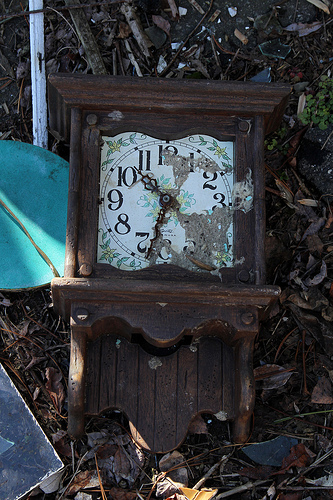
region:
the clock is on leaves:
[0, 0, 332, 498]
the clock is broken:
[91, 124, 257, 284]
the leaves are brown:
[0, 2, 332, 499]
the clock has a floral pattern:
[100, 130, 235, 269]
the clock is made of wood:
[47, 71, 280, 450]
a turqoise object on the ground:
[0, 138, 65, 291]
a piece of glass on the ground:
[0, 436, 15, 455]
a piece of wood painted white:
[26, 0, 45, 146]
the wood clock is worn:
[45, 72, 281, 452]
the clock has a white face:
[102, 135, 232, 266]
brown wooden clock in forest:
[43, 68, 296, 447]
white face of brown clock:
[52, 67, 289, 459]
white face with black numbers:
[96, 131, 236, 265]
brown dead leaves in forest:
[6, 0, 331, 495]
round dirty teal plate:
[1, 139, 75, 297]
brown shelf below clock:
[47, 68, 281, 469]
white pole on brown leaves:
[28, 0, 47, 158]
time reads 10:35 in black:
[92, 127, 242, 270]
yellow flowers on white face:
[93, 126, 239, 273]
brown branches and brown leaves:
[4, 2, 331, 498]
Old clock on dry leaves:
[35, 39, 284, 459]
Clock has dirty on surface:
[92, 116, 244, 277]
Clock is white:
[94, 131, 236, 275]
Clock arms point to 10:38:
[129, 160, 182, 259]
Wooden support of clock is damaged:
[38, 55, 286, 471]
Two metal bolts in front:
[61, 299, 264, 327]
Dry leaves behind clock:
[11, 2, 329, 494]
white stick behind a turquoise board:
[25, 1, 50, 156]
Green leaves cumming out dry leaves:
[271, 68, 332, 156]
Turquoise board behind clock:
[2, 132, 72, 298]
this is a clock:
[99, 134, 234, 268]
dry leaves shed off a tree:
[92, 454, 274, 498]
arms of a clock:
[131, 162, 175, 259]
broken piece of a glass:
[257, 37, 292, 59]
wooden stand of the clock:
[71, 360, 257, 451]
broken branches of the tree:
[197, 459, 268, 496]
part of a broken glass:
[1, 366, 67, 498]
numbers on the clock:
[107, 166, 136, 237]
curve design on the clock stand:
[90, 409, 159, 442]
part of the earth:
[111, 456, 196, 495]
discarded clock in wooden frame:
[44, 30, 300, 461]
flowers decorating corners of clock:
[84, 124, 237, 274]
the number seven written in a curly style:
[131, 225, 149, 254]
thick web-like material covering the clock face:
[139, 130, 252, 271]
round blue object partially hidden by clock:
[3, 120, 70, 302]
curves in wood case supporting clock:
[63, 293, 255, 460]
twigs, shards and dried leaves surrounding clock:
[200, 341, 317, 487]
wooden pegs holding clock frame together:
[68, 259, 254, 334]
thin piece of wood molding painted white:
[21, 9, 54, 153]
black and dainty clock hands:
[123, 150, 185, 261]